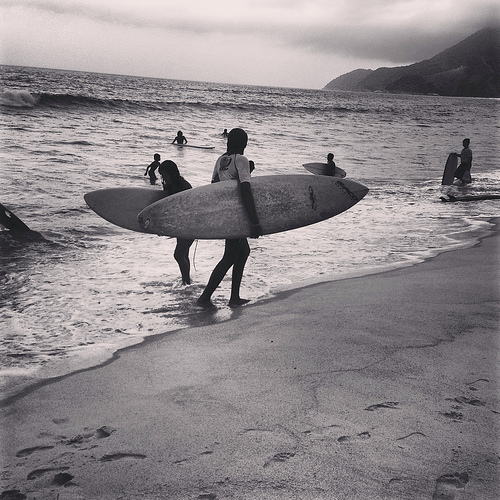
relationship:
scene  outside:
[3, 3, 495, 498] [3, 1, 496, 495]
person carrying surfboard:
[191, 124, 267, 314] [131, 170, 372, 243]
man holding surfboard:
[452, 137, 474, 184] [439, 147, 461, 190]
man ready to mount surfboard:
[170, 129, 187, 150] [165, 135, 218, 153]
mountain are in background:
[319, 25, 499, 96] [9, 1, 486, 129]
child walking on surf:
[143, 153, 161, 187] [1, 64, 498, 412]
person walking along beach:
[194, 125, 266, 314] [1, 213, 498, 496]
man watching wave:
[452, 137, 474, 184] [13, 89, 350, 112]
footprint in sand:
[436, 463, 470, 488] [399, 434, 483, 498]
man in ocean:
[170, 129, 187, 150] [0, 64, 499, 406]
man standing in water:
[452, 137, 474, 184] [374, 125, 471, 206]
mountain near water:
[319, 43, 462, 90] [292, 89, 462, 159]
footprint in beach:
[334, 428, 376, 446] [0, 231, 499, 499]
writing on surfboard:
[334, 181, 361, 201] [139, 172, 370, 240]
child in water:
[143, 153, 161, 187] [46, 128, 190, 183]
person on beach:
[194, 125, 266, 314] [0, 110, 455, 486]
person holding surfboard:
[194, 125, 266, 314] [134, 175, 362, 237]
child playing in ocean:
[144, 153, 161, 185] [5, 80, 484, 307]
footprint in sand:
[430, 469, 472, 499] [275, 330, 477, 495]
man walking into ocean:
[453, 137, 473, 189] [9, 62, 469, 195]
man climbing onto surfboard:
[173, 128, 187, 148] [169, 140, 215, 151]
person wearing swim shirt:
[194, 125, 266, 314] [213, 150, 250, 184]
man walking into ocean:
[321, 150, 336, 173] [16, 95, 473, 274]